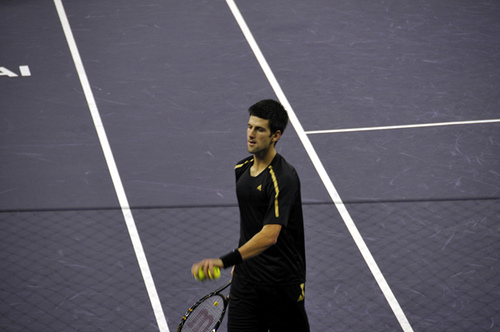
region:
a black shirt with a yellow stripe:
[225, 144, 309, 296]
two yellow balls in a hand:
[186, 253, 227, 282]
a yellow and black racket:
[173, 273, 237, 330]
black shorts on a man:
[221, 288, 313, 329]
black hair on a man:
[241, 94, 296, 145]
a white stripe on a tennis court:
[51, 7, 178, 330]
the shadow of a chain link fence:
[2, 187, 496, 330]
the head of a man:
[240, 90, 297, 157]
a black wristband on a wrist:
[221, 243, 246, 268]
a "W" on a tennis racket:
[190, 302, 219, 329]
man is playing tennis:
[175, 100, 312, 330]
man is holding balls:
[188, 255, 223, 282]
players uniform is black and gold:
[217, 149, 312, 330]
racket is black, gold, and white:
[170, 281, 226, 329]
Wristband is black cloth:
[217, 248, 246, 268]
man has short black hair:
[243, 98, 288, 148]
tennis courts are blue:
[1, 1, 499, 331]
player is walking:
[171, 93, 313, 330]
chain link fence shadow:
[1, 198, 498, 329]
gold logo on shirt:
[252, 183, 267, 194]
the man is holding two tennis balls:
[183, 248, 238, 290]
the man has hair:
[257, 96, 280, 121]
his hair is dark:
[245, 97, 280, 112]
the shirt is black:
[215, 155, 305, 270]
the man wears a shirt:
[225, 161, 310, 271]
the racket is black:
[170, 286, 227, 327]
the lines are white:
[291, 115, 357, 196]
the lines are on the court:
[305, 120, 381, 210]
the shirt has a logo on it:
[247, 175, 267, 195]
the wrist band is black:
[210, 249, 250, 270]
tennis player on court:
[186, 88, 323, 317]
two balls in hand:
[180, 251, 232, 291]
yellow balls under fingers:
[188, 263, 223, 285]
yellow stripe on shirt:
[263, 163, 284, 222]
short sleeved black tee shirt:
[229, 154, 309, 286]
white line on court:
[300, 123, 346, 193]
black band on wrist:
[212, 243, 247, 269]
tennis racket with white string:
[185, 278, 237, 330]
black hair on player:
[249, 96, 288, 126]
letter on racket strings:
[188, 303, 218, 330]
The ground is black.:
[129, 26, 216, 112]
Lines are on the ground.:
[42, 5, 304, 90]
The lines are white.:
[44, 2, 148, 166]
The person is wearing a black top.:
[208, 150, 343, 270]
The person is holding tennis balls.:
[178, 240, 233, 285]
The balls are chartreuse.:
[189, 255, 234, 280]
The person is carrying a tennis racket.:
[160, 277, 241, 330]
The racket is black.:
[156, 275, 238, 329]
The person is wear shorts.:
[202, 265, 325, 330]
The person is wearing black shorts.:
[210, 272, 332, 329]